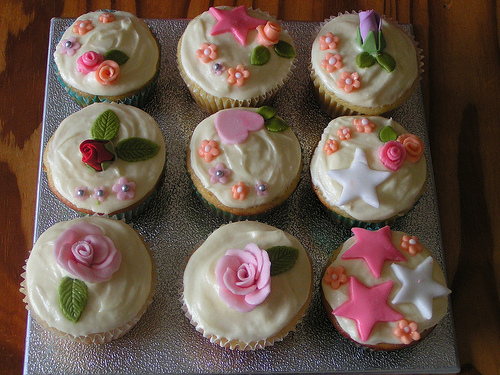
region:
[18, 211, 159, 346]
white frosted cupcake with a pink rose design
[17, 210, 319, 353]
two white frosted cupcakes with rose designs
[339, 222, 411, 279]
pink star design on top of a cupcake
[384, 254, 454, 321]
white star design on a cupcake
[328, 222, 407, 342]
two pink stars on a cupcake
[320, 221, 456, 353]
pink and white stars on a cupcake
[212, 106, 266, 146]
pink heart design on a cupcake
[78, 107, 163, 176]
red rose and green leaves design on a cupcake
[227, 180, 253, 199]
small orange floral design on a cupcake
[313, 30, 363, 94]
three small orange floral designs on a cupcake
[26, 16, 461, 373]
textured silver tray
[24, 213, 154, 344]
white frosted cupcake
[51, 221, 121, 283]
pink rose on top of cupcake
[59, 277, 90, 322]
green leaf next to rose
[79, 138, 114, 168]
red rose on top of cupcake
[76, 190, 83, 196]
silver bead on a pink flower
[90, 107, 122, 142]
green leaf next to a rose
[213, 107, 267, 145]
pink fondant hear on top of cupcake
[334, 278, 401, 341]
pink fondant star next to white star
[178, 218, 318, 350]
cupcake on top of tray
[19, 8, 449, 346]
nine decorated cupcakes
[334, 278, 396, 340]
a pink star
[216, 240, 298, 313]
a pink rose made of icing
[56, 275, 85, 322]
green leaf made of icing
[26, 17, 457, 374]
cupcakes are on a silver platform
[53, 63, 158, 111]
light blue cupcake wrapper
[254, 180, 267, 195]
flower with a silver bead on it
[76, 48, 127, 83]
two frosting roses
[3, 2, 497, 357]
a wooden table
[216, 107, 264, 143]
a pink heart sugar cutout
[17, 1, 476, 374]
tray of decorated cupcakes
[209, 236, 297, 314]
light pink icing flower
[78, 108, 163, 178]
red rose icing flower with green leaves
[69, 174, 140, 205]
three icing flowers with pearl centers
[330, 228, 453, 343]
pink and white icing stars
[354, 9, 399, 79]
purple icing rose bud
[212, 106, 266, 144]
light pink heart made out of icing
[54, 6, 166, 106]
cupcake with white icing and colored edible flowers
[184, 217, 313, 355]
cupcake with white frosting and pink rose